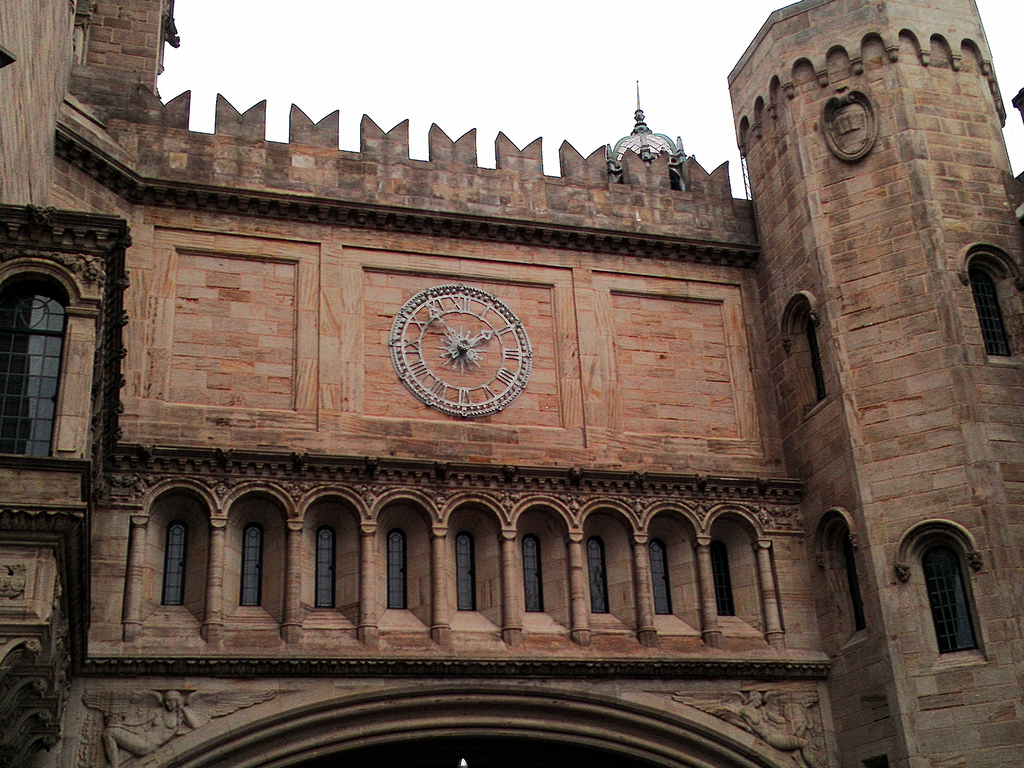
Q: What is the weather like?
A: It is cloudy.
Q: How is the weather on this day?
A: It is cloudy.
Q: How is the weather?
A: It is cloudy.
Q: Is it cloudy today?
A: Yes, it is cloudy.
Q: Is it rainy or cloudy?
A: It is cloudy.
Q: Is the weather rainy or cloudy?
A: It is cloudy.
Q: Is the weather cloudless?
A: No, it is cloudy.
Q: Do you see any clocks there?
A: Yes, there is a clock.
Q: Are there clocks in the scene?
A: Yes, there is a clock.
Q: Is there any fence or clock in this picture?
A: Yes, there is a clock.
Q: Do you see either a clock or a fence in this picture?
A: Yes, there is a clock.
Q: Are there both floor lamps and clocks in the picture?
A: No, there is a clock but no floor lamps.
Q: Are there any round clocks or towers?
A: Yes, there is a round clock.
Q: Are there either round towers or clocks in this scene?
A: Yes, there is a round clock.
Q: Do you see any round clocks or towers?
A: Yes, there is a round clock.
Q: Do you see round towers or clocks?
A: Yes, there is a round clock.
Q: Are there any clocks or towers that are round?
A: Yes, the clock is round.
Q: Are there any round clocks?
A: Yes, there is a round clock.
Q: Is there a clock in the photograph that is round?
A: Yes, there is a clock that is round.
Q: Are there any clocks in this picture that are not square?
A: Yes, there is a round clock.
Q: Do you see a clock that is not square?
A: Yes, there is a round clock.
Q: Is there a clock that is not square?
A: Yes, there is a round clock.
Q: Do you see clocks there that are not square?
A: Yes, there is a round clock.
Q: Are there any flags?
A: No, there are no flags.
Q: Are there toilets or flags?
A: No, there are no flags or toilets.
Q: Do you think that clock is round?
A: Yes, the clock is round.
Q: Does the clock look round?
A: Yes, the clock is round.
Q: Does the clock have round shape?
A: Yes, the clock is round.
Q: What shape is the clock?
A: The clock is round.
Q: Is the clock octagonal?
A: No, the clock is round.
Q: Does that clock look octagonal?
A: No, the clock is round.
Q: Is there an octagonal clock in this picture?
A: No, there is a clock but it is round.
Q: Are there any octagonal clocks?
A: No, there is a clock but it is round.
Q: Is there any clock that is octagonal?
A: No, there is a clock but it is round.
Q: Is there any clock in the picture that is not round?
A: No, there is a clock but it is round.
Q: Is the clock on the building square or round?
A: The clock is round.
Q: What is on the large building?
A: The clock is on the building.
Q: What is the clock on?
A: The clock is on the building.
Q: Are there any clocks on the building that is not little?
A: Yes, there is a clock on the building.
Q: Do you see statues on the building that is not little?
A: No, there is a clock on the building.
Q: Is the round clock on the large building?
A: Yes, the clock is on the building.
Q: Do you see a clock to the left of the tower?
A: Yes, there is a clock to the left of the tower.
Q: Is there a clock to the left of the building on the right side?
A: Yes, there is a clock to the left of the tower.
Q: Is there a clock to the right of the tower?
A: No, the clock is to the left of the tower.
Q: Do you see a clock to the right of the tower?
A: No, the clock is to the left of the tower.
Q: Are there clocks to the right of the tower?
A: No, the clock is to the left of the tower.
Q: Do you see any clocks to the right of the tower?
A: No, the clock is to the left of the tower.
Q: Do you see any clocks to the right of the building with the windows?
A: No, the clock is to the left of the tower.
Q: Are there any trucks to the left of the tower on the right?
A: No, there is a clock to the left of the tower.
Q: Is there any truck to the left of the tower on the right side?
A: No, there is a clock to the left of the tower.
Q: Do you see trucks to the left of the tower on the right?
A: No, there is a clock to the left of the tower.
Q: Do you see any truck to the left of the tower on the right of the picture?
A: No, there is a clock to the left of the tower.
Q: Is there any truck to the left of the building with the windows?
A: No, there is a clock to the left of the tower.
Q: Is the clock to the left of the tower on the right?
A: Yes, the clock is to the left of the tower.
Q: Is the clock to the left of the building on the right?
A: Yes, the clock is to the left of the tower.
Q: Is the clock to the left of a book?
A: No, the clock is to the left of the tower.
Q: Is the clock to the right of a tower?
A: No, the clock is to the left of a tower.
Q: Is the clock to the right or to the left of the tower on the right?
A: The clock is to the left of the tower.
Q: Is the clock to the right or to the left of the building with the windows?
A: The clock is to the left of the tower.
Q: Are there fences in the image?
A: No, there are no fences.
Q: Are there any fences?
A: No, there are no fences.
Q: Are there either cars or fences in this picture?
A: No, there are no fences or cars.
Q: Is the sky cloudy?
A: Yes, the sky is cloudy.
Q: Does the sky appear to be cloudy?
A: Yes, the sky is cloudy.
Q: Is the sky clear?
A: No, the sky is cloudy.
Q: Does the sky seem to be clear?
A: No, the sky is cloudy.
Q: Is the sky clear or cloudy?
A: The sky is cloudy.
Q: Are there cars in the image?
A: No, there are no cars.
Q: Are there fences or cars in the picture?
A: No, there are no cars or fences.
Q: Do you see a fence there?
A: No, there are no fences.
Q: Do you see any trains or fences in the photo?
A: No, there are no fences or trains.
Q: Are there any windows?
A: Yes, there is a window.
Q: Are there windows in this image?
A: Yes, there is a window.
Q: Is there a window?
A: Yes, there is a window.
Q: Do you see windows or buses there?
A: Yes, there is a window.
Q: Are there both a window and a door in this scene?
A: No, there is a window but no doors.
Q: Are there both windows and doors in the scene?
A: No, there is a window but no doors.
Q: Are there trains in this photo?
A: No, there are no trains.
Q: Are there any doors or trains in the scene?
A: No, there are no trains or doors.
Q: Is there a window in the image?
A: Yes, there is a window.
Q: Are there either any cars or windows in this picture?
A: Yes, there is a window.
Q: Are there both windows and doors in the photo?
A: No, there is a window but no doors.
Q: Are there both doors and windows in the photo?
A: No, there is a window but no doors.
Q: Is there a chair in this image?
A: No, there are no chairs.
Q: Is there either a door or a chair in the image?
A: No, there are no chairs or doors.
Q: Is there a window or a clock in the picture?
A: Yes, there is a window.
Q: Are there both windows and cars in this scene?
A: No, there is a window but no cars.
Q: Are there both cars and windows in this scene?
A: No, there is a window but no cars.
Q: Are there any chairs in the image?
A: No, there are no chairs.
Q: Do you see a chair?
A: No, there are no chairs.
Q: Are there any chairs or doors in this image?
A: No, there are no chairs or doors.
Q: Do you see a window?
A: Yes, there is a window.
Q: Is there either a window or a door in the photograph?
A: Yes, there is a window.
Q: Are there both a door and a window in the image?
A: No, there is a window but no doors.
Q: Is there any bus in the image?
A: No, there are no buses.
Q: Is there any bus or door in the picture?
A: No, there are no buses or doors.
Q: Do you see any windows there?
A: Yes, there is a window.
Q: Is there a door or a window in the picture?
A: Yes, there is a window.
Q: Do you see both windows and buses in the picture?
A: No, there is a window but no buses.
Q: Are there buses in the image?
A: No, there are no buses.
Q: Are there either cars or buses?
A: No, there are no buses or cars.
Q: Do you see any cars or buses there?
A: No, there are no buses or cars.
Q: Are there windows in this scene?
A: Yes, there is a window.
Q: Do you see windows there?
A: Yes, there is a window.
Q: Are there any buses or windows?
A: Yes, there is a window.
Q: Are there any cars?
A: No, there are no cars.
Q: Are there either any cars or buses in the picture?
A: No, there are no cars or buses.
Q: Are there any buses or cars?
A: No, there are no cars or buses.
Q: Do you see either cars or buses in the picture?
A: No, there are no cars or buses.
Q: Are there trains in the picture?
A: No, there are no trains.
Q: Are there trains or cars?
A: No, there are no trains or cars.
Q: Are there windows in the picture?
A: Yes, there is a window.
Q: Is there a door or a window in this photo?
A: Yes, there is a window.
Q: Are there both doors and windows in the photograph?
A: No, there is a window but no doors.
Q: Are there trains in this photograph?
A: No, there are no trains.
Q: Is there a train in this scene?
A: No, there are no trains.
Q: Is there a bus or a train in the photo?
A: No, there are no trains or buses.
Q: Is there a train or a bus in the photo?
A: No, there are no trains or buses.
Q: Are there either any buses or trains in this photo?
A: No, there are no trains or buses.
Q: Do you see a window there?
A: Yes, there is a window.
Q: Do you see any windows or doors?
A: Yes, there is a window.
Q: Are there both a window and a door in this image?
A: No, there is a window but no doors.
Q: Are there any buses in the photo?
A: No, there are no buses.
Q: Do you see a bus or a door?
A: No, there are no buses or doors.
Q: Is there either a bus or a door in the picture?
A: No, there are no buses or doors.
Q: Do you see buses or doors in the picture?
A: No, there are no buses or doors.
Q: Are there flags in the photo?
A: No, there are no flags.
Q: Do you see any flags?
A: No, there are no flags.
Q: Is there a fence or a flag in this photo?
A: No, there are no flags or fences.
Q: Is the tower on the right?
A: Yes, the tower is on the right of the image.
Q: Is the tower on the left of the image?
A: No, the tower is on the right of the image.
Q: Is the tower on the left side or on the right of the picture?
A: The tower is on the right of the image.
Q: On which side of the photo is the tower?
A: The tower is on the right of the image.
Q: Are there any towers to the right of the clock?
A: Yes, there is a tower to the right of the clock.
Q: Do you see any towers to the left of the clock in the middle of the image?
A: No, the tower is to the right of the clock.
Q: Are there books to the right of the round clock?
A: No, there is a tower to the right of the clock.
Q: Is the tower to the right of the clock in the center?
A: Yes, the tower is to the right of the clock.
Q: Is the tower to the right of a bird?
A: No, the tower is to the right of the clock.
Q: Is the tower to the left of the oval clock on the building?
A: No, the tower is to the right of the clock.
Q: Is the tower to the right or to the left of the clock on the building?
A: The tower is to the right of the clock.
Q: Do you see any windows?
A: Yes, there are windows.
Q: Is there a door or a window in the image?
A: Yes, there are windows.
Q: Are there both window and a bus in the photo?
A: No, there are windows but no buses.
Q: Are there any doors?
A: No, there are no doors.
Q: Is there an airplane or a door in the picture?
A: No, there are no doors or airplanes.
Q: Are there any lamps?
A: No, there are no lamps.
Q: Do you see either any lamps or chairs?
A: No, there are no lamps or chairs.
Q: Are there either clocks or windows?
A: Yes, there are windows.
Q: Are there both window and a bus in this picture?
A: No, there are windows but no buses.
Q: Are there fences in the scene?
A: No, there are no fences.